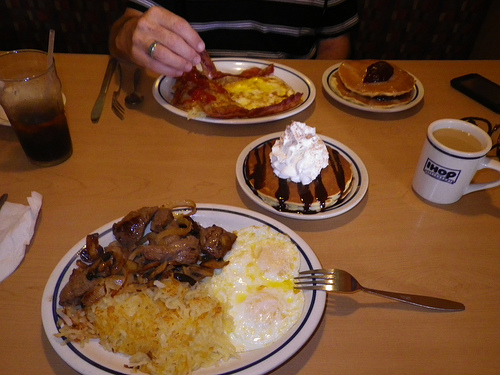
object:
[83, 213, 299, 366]
food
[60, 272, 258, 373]
hash browns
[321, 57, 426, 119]
plate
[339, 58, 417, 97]
pancakes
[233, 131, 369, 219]
plate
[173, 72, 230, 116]
bacon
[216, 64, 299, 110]
eggs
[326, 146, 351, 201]
chocolate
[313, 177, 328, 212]
chocolate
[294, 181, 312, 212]
chocolate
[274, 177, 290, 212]
chocolate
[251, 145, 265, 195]
chocolate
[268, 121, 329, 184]
cream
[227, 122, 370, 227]
pancake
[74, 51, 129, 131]
knife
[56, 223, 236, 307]
steak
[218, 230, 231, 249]
mushroom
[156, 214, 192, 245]
onion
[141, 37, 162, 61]
ring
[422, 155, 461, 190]
writing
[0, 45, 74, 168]
cup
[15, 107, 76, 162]
soda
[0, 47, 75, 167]
glass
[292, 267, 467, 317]
fork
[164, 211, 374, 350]
eggs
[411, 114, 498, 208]
cup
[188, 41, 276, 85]
bacon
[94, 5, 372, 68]
person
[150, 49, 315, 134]
plate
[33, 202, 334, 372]
plate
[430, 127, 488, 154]
coffee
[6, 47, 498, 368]
table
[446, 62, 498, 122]
cell phone